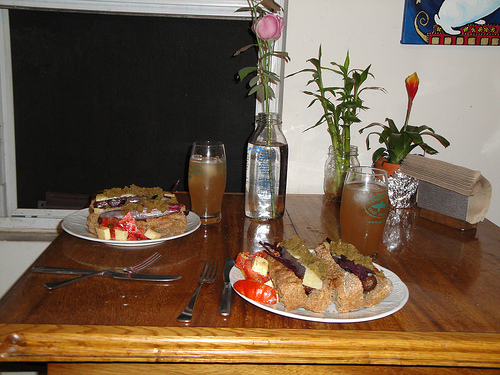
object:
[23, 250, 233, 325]
silverware.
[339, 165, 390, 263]
glass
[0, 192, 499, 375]
brown table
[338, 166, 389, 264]
beverage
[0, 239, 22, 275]
ground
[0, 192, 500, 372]
table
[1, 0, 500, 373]
home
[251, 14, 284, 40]
flower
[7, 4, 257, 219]
window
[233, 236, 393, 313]
meal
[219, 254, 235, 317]
knife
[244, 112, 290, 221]
glass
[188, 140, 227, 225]
glass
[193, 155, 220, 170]
ice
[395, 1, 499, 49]
poster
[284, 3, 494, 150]
wall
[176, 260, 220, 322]
fork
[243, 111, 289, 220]
vase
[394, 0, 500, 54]
picture wall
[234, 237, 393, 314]
dinner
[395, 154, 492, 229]
napkins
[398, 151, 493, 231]
holder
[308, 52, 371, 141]
flower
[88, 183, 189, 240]
meal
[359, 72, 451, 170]
plant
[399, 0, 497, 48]
picture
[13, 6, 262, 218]
screen